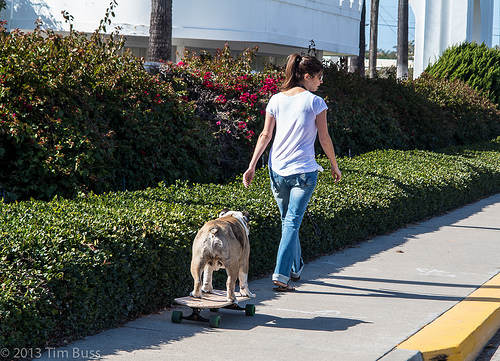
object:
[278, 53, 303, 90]
ponytail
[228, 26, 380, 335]
girl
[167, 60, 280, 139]
flowers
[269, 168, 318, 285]
jeans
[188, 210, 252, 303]
dog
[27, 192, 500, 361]
pavement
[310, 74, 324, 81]
glasses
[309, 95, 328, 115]
sleeve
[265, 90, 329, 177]
shirt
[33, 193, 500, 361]
sidewalk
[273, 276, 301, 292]
sandals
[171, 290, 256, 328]
skateboard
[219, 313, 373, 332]
shadow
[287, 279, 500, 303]
shadow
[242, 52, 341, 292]
girl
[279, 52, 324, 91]
hair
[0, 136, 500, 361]
bush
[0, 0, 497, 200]
bush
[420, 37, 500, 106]
bush